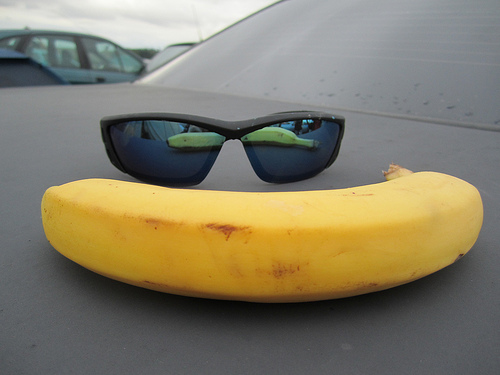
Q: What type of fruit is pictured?
A: Banana.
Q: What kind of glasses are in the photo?
A: Sunglasses.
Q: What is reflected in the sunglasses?
A: Banana.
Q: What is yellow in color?
A: A banana.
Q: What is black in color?
A: Sunglass.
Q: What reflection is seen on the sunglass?
A: Reflection of banana.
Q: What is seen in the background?
A: Blue sedan.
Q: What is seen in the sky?
A: Clouds.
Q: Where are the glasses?
A: On a surface.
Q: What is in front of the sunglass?
A: A banana.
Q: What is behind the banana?
A: Sunglass.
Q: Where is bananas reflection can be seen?
A: On the sunglass.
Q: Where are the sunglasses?
A: On hood.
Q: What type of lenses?
A: Reflective.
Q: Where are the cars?
A: In background.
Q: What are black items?
A: Sunglasses.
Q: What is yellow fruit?
A: Banana.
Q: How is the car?
A: Parked.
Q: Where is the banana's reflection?
A: On sunglasses.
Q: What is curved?
A: The banana.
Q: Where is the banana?
A: On a car.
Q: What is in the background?
A: A blue car.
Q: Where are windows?
A: On blue car.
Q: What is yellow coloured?
A: Banana.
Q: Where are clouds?
A: In the sky.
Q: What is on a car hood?
A: A banana.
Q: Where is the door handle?
A: On blue car.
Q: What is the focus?
A: Banana glasses.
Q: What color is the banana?
A: Yellow.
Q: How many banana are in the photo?
A: 1.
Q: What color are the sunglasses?
A: Black.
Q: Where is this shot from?
A: Car trunk.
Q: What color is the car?
A: Grey.